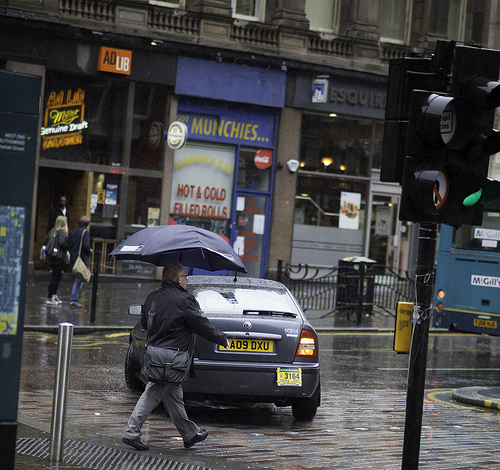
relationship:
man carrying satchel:
[119, 251, 230, 453] [138, 294, 195, 386]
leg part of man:
[122, 367, 174, 454] [120, 259, 210, 449]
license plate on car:
[212, 336, 274, 353] [122, 273, 322, 423]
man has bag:
[119, 251, 230, 453] [139, 340, 192, 385]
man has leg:
[119, 251, 230, 453] [163, 378, 209, 448]